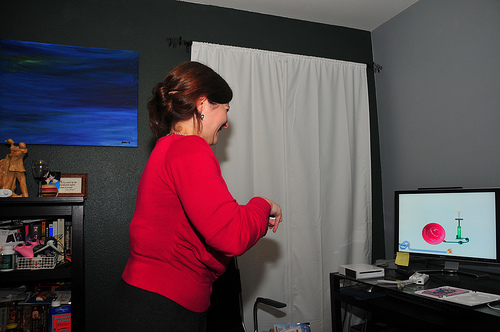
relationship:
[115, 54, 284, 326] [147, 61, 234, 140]
lady has hair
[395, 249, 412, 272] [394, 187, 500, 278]
note on computer monitor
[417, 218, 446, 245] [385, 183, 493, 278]
ball on screen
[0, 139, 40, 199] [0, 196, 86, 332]
figurine on book case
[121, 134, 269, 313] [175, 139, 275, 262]
shirt has sleeves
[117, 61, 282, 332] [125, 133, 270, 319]
lady is wearing shirt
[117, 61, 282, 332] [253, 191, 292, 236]
lady is holding controller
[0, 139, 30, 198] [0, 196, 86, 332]
figurine on book case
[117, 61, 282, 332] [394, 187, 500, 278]
lady looking at computer monitor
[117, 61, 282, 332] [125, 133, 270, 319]
lady wearing shirt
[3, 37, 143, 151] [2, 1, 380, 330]
painting on wall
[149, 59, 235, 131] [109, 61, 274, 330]
hair on woman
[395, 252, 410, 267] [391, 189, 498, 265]
note on monitor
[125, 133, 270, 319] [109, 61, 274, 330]
shirt on woman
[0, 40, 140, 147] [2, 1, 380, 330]
painting on wall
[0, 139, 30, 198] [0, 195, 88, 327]
figurine on book case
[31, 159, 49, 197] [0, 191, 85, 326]
glass on bookcase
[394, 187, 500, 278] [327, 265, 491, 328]
computer monitor on desk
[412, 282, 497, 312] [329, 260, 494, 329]
book on desk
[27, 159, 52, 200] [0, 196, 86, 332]
glass on book case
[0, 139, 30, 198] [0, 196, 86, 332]
figurine on top of book case